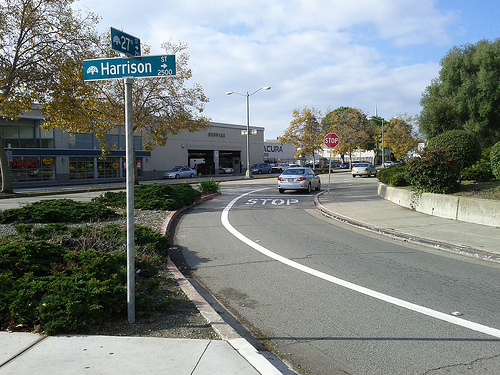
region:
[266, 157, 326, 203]
small silver sedan on road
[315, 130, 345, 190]
red stop sign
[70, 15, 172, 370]
two green street signs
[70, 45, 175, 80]
sign for Harrison Street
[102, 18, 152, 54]
sign for 27th street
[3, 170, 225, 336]
green shrubs in a median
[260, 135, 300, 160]
white Acura building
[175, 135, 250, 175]
automotive garage with two bays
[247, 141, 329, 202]
car making a turn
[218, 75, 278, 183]
white street lights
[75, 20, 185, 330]
a street sign for the intersection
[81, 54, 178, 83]
a sign for Harrison Street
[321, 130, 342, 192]
a stop sign on the corner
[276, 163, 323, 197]
a silver car passing the stop sign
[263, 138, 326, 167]
an Acura dealership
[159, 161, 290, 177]
cars parked on the side of the street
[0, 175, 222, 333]
a median landscaped with bushes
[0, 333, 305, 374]
a sidewalk near the street sign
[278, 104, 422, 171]
three trees with yellow leaves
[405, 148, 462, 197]
a bush with red flowers blooming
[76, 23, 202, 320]
street sign on pole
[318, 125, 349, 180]
stop sign on pole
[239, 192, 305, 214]
STOP painted on road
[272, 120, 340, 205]
car at stop sign on road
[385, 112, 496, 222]
cement wall and landscaping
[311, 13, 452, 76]
sky with clouds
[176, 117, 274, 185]
garage bays on building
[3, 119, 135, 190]
storefront with windows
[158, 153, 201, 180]
car parked by building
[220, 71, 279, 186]
street lights on pole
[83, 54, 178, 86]
street sign of Harrison Street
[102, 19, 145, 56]
street sign for 27th street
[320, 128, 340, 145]
stop sign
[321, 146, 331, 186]
galvanized steel post of stop sign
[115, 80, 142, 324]
galvanized steel post of street sign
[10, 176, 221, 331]
shrubbery on the left street curved corner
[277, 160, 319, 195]
grey car stopped at stop sign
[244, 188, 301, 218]
stop written in white paint on the road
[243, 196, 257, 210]
the letter S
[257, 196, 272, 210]
the letter T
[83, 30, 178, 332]
street signs on a metal pole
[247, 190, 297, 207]
the word "STOP" written on road in white paint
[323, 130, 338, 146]
a red and white stop sign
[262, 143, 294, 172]
a building with the word "Acura" on it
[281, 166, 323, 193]
a small silver sedan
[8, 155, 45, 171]
the word "savings" written in red on window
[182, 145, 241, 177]
a pair of open garages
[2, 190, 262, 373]
grey colored cement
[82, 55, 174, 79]
street sign showing Harrison St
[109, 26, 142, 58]
street sign showing 27th street